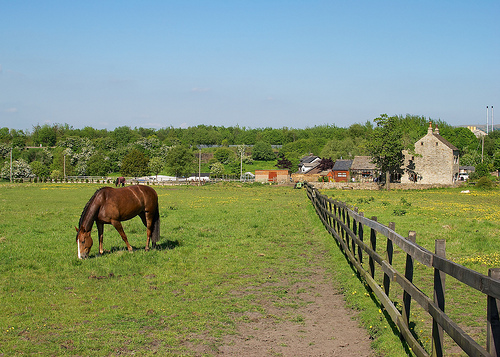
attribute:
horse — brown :
[71, 181, 161, 260]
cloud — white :
[341, 32, 433, 88]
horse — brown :
[44, 167, 211, 258]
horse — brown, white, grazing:
[66, 177, 165, 254]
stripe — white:
[76, 239, 82, 261]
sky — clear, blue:
[53, 26, 478, 100]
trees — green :
[74, 125, 325, 160]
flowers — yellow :
[246, 187, 266, 204]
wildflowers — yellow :
[39, 183, 85, 192]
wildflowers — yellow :
[459, 250, 499, 267]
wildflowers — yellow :
[213, 198, 239, 204]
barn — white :
[399, 120, 463, 189]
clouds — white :
[9, 87, 84, 117]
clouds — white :
[144, 84, 227, 114]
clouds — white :
[245, 70, 327, 109]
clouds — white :
[366, 50, 486, 102]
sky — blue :
[1, 1, 497, 122]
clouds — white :
[15, 20, 125, 83]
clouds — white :
[154, 15, 294, 83]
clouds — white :
[389, 18, 499, 72]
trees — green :
[0, 125, 83, 185]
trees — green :
[243, 125, 356, 180]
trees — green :
[349, 113, 412, 184]